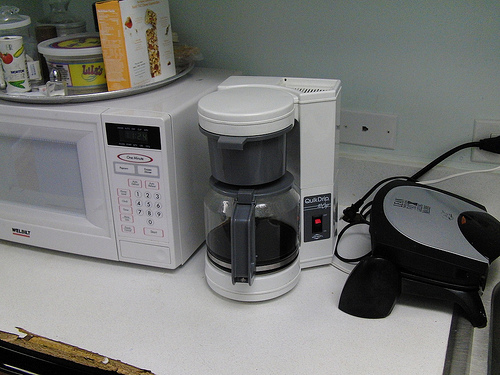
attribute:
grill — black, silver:
[338, 177, 499, 329]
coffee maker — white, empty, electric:
[196, 74, 342, 302]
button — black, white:
[119, 238, 172, 264]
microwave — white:
[1, 66, 242, 270]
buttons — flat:
[112, 149, 165, 238]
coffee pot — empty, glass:
[202, 169, 302, 285]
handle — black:
[227, 200, 257, 286]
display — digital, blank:
[106, 122, 163, 149]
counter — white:
[0, 182, 455, 374]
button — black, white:
[154, 210, 164, 220]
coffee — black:
[205, 215, 297, 273]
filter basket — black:
[197, 123, 294, 185]